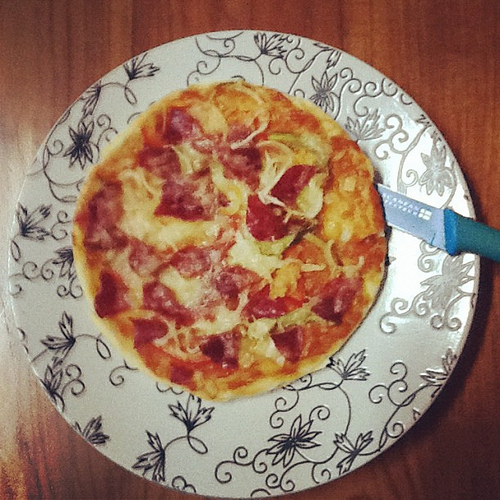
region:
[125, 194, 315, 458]
a pizza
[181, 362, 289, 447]
a pizza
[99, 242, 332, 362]
a pizza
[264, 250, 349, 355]
a pizza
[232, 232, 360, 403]
a pizza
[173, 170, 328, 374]
a pizza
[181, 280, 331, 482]
a pizza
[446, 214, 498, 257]
a blue handle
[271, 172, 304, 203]
pepperoni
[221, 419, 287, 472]
the design on the pizza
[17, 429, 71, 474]
the brown table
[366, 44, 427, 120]
the plate is on the brown table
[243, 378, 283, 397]
crust of the pizza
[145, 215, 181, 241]
cheese on the pizza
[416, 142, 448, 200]
the design is black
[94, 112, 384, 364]
the pizza is small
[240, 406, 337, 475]
the plate is black and white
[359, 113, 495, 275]
knife with blue handle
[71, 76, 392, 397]
individual sized pizza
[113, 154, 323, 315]
meat and cheese with sauce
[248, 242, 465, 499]
plate with imprint of vines and flowers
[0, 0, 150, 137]
a wood look table top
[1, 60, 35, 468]
light reflected off table top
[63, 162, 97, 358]
thin crust of pizza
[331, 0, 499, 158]
a verticle wood grain pattern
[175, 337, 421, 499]
filigree vines in black on white plate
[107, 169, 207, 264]
area of melted cheese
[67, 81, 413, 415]
A cooked pizza on a plate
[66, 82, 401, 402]
Pizza is in the shape of a circle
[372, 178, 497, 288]
A cutting knife on the plate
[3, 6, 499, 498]
Plate is on a wooden surface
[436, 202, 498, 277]
Cutting knife has a blue handle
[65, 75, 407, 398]
Pizza has dark red toppings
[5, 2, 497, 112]
Surface wood is carmel brown in color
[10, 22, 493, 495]
Plate has black leaf designs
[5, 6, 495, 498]
Photo was taken indoors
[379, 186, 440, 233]
Knife has writing on its blade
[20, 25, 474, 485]
large and round plate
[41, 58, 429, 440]
plate has black design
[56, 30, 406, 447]
plate has floral design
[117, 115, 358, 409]
small pizza on plate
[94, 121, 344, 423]
pizza has golden crust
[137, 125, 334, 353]
red pepperoni on pizza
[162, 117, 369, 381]
yellow cheese on pizza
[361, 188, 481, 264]
steel knife under pizza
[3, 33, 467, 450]
plate on brown table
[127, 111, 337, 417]
small and round pizza